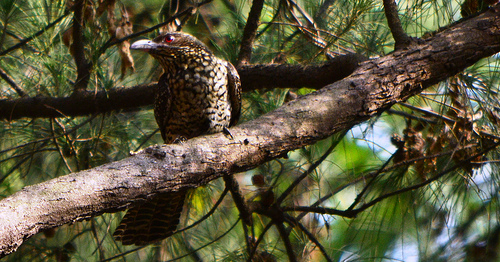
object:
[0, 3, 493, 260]
log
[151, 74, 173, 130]
left wing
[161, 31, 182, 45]
eye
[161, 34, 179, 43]
eyes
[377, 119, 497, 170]
pinecones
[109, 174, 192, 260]
tail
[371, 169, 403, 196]
ground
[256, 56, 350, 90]
branches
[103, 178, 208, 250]
tail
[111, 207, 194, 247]
bird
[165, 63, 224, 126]
bird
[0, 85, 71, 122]
branch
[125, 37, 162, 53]
beak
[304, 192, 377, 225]
branch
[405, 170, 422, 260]
pine needle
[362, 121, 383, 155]
pine needle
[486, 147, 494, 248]
pine needle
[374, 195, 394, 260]
pine needle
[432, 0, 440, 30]
pine needle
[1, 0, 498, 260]
pine tree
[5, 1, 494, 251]
tree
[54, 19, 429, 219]
tree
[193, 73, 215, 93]
bird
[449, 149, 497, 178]
branch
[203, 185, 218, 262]
pine needles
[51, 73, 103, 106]
branches